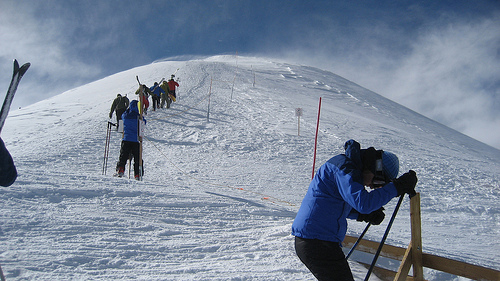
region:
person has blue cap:
[359, 137, 436, 179]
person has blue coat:
[262, 166, 411, 242]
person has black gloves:
[380, 151, 424, 205]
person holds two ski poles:
[342, 172, 417, 274]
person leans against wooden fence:
[314, 182, 499, 271]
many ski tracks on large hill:
[70, 79, 280, 278]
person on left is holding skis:
[2, 30, 35, 116]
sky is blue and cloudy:
[60, 6, 188, 79]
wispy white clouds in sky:
[2, 7, 154, 74]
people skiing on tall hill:
[108, 61, 211, 200]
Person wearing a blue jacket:
[291, 130, 412, 270]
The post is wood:
[397, 190, 436, 280]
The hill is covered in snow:
[10, 38, 487, 268]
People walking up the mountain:
[103, 69, 180, 131]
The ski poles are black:
[336, 184, 410, 280]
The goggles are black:
[368, 144, 401, 190]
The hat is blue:
[365, 141, 402, 188]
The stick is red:
[301, 92, 324, 182]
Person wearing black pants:
[115, 92, 150, 179]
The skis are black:
[1, 56, 33, 151]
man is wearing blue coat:
[287, 122, 394, 279]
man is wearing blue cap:
[370, 124, 420, 184]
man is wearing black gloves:
[365, 159, 427, 194]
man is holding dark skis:
[311, 180, 410, 279]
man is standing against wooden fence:
[321, 180, 483, 266]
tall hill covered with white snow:
[75, 52, 314, 268]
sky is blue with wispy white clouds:
[312, 7, 499, 119]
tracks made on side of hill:
[260, 58, 462, 208]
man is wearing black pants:
[300, 230, 335, 277]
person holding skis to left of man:
[0, 51, 40, 169]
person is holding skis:
[11, 60, 30, 125]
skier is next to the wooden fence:
[293, 147, 401, 279]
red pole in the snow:
[309, 88, 331, 161]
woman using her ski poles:
[356, 182, 410, 262]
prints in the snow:
[265, 52, 318, 88]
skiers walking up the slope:
[130, 79, 200, 101]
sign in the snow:
[284, 106, 312, 134]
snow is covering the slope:
[173, 188, 223, 278]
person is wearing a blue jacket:
[309, 178, 332, 222]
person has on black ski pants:
[314, 237, 337, 272]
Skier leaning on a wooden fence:
[266, 135, 497, 278]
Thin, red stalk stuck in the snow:
[306, 94, 325, 182]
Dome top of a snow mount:
[137, 46, 327, 90]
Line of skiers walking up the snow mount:
[105, 63, 180, 188]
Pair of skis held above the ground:
[0, 51, 34, 133]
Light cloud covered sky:
[3, 9, 498, 69]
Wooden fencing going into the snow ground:
[336, 191, 497, 278]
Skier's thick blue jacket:
[283, 142, 420, 248]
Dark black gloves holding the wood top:
[390, 167, 422, 199]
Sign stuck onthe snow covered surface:
[292, 103, 303, 141]